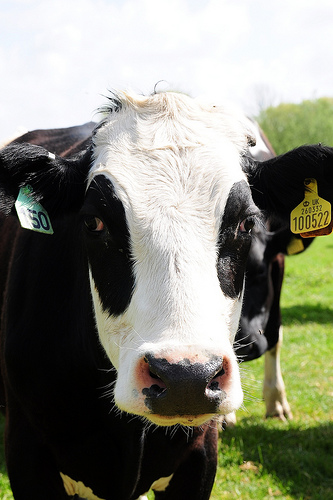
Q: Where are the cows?
A: In a field.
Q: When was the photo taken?
A: Daytime.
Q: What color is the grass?
A: Green.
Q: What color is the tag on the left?
A: Blye.